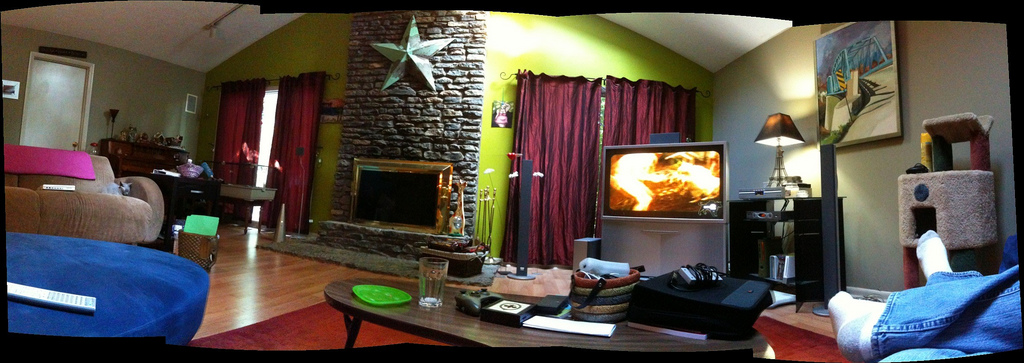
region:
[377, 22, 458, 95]
a star hanging over a fire place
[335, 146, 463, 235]
a fire place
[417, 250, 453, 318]
a clear glass on a table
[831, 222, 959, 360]
a person's feet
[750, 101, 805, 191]
a lamp on a stand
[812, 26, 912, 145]
a large picture hanging on the wall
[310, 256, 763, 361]
a wood table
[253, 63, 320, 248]
a red curtain covering a wall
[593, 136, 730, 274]
television in the living room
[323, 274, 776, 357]
wooden coffee table in the room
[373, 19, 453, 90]
large metal star over the fireplace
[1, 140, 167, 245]
tan couch in the room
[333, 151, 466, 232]
brass fireplace in the room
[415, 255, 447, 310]
empty glass on the table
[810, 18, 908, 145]
abstract painting on the wall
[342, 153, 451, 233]
gold colored fireplace insert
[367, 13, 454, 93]
large bronze star on the fireplace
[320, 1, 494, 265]
large stone fireplace and chimney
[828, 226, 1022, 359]
a person's legs and feet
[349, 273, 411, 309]
green plate on a coffee table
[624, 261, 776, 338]
black binder on coffee table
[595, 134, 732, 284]
large wide screen television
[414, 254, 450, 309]
drinking glass on the coffee table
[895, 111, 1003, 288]
cat house covered in carpet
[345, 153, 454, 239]
A gold fireplace with black middle.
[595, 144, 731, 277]
A grey television that is on.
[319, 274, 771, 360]
A brown coffee table.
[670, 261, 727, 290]
A grey and black controller on a coffee table.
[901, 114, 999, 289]
A multi storied cat house.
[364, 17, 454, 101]
A large silver star on a rock wall.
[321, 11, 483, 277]
A strip of rock fireplace.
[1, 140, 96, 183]
Pink blanket on the couch back.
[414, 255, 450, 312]
Clear glass on a table top.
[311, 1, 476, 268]
Stone fireplace in living room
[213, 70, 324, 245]
Partially open drapes in living room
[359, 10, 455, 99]
Decorative star wall hanging on fireplace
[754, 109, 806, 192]
Lamp that is on in living room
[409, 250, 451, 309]
Empty glass on coffee table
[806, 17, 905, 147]
Painting on wall in living room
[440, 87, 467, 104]
a stone in a wall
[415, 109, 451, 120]
a stone in a wall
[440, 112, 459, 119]
a stone in a wall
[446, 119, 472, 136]
a stone in a wall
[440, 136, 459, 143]
a stone in a wall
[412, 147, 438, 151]
a stone in a wall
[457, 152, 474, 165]
a stone in a wall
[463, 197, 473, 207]
a stone in a wall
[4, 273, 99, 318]
a remote control on top of a blue sofa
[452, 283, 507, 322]
a game controller pad on top of a table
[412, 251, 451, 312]
a glass cup on top of a wooden table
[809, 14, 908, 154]
a painting on a wall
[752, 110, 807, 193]
a lamp on top of a shelf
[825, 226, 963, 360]
a person wearing white socks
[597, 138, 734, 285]
a silver project screen television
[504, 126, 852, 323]
surround sound speakers near a television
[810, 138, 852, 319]
a surround sound speaker in front of a painting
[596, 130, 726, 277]
a tall gray t.v.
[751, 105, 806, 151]
a black lampshade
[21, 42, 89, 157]
a white roofm door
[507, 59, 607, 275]
tall red curtains